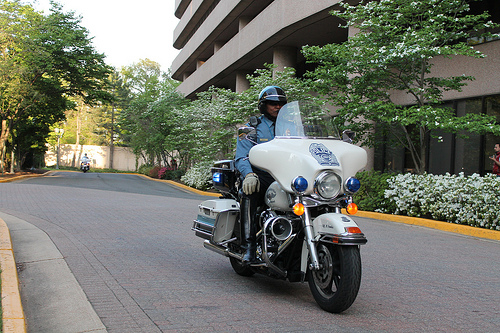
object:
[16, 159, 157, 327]
pavement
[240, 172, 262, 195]
hand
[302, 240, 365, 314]
wheel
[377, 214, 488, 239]
yellow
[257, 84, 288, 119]
helmet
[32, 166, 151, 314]
road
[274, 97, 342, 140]
windshield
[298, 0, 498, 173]
trees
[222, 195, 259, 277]
wheels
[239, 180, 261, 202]
knee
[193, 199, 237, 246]
cargo space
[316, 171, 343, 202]
headlight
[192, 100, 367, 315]
cycle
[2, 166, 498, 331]
street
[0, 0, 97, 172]
tree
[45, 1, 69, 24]
leaves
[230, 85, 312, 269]
officer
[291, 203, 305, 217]
side light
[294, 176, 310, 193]
blue light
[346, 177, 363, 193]
blue light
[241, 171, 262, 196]
glove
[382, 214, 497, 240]
strip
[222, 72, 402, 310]
patrol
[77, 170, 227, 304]
downhill